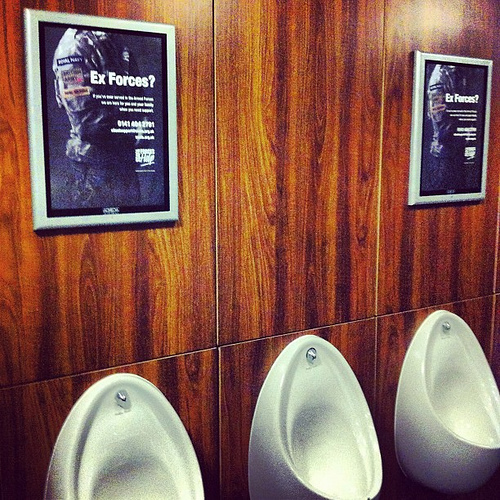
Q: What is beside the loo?
A: Wall.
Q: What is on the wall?
A: Stickers.